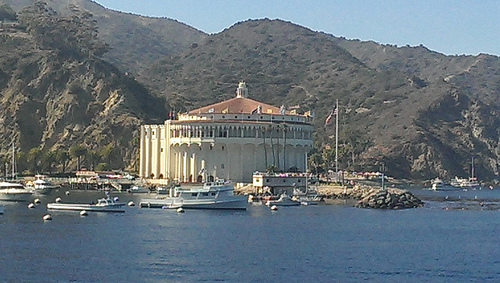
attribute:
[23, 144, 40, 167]
leaves — green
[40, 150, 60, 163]
leaves — green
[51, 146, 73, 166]
leaves — green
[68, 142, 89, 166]
leaves — green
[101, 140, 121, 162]
leaves — green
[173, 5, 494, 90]
sky — blue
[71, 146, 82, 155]
leaves — green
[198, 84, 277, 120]
roof — red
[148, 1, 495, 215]
mountain — brown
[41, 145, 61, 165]
leaves — green